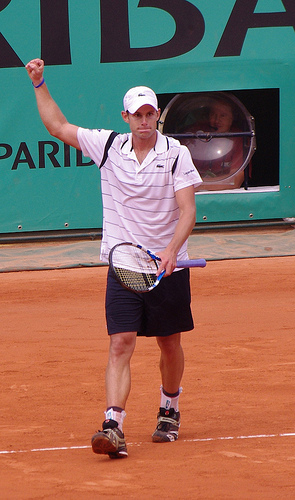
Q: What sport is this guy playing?
A: Tennis.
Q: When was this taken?
A: During a match.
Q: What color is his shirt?
A: Pink.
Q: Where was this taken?
A: On a tennis court.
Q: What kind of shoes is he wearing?
A: Tennis shoes.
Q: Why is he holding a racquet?
A: He is playing tennis.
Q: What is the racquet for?
A: To play tennis.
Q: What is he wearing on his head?
A: A hat.